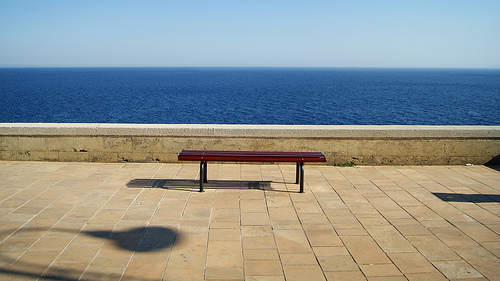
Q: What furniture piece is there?
A: Bench.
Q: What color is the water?
A: Blue.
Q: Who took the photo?
A: Tourist.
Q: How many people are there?
A: Zero.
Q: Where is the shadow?
A: Left.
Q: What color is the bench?
A: Brown.